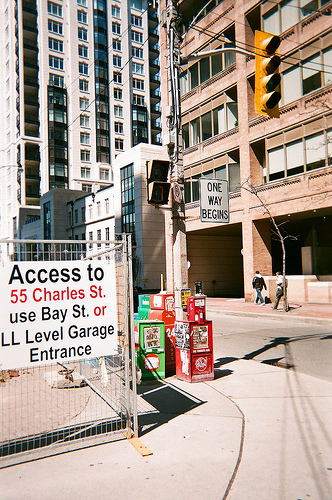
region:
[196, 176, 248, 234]
black and white traffic sign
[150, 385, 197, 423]
shadow on the sidewalk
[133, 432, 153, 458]
wooden plank under a fence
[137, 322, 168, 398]
a green newspaper machine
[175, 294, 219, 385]
a red newspaper machine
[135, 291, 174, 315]
newspaper machines on the curb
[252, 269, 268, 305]
a man wearing a black leather jacket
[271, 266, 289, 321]
a man walking down the street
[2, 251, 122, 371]
a white sign with red and black lettering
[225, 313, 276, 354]
empty city street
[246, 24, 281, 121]
a yellow traffic light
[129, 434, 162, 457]
a wooden plank on the ground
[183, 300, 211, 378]
a red newspaper box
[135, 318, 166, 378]
a green newspaper dispenser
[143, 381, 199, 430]
a shadow on the sidewalk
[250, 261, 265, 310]
a man in black leather jacket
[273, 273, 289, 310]
a man walking down the sidewalk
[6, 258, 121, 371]
a white sign with black and red letters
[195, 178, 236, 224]
a black and white traffic sign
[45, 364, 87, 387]
a cement slab on the ground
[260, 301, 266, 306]
the shoe of a man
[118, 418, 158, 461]
part of a wooden plank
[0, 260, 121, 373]
a large sign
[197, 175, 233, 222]
a black and white sign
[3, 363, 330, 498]
part of a sidewalk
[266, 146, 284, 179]
a window of a building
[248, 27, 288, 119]
a tall yellow street light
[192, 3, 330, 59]
a long electrical power line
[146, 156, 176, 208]
a pedestrian street light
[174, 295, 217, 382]
a tall red paper dispenser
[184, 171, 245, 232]
white sign on a pole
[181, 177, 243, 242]
the letters are black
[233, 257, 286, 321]
people walking across the street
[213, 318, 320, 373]
shadow of the pole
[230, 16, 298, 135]
the traffic light is yellow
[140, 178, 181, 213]
the number 7 is lit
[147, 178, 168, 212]
the number 7 is orange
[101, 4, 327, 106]
wires above the street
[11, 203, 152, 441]
the fence is grey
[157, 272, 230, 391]
a newspaper dispenser on the sidewalk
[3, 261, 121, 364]
white sign on fence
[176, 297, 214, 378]
red metal newspaper box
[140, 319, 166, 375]
green metal newspaper box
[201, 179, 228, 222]
white and black street sign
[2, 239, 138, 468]
grey metal link fence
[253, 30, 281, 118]
yellow electric stop light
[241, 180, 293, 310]
tree with no leaves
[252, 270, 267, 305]
man wearing leather jacket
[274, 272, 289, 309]
man walking on sidewalk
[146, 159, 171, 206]
walk and don't walk box